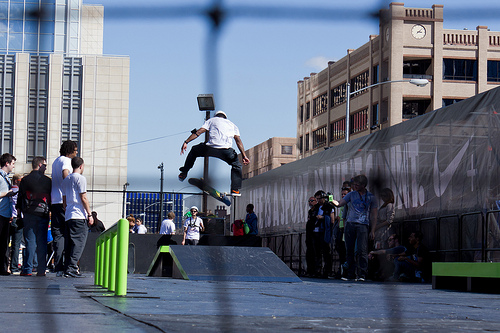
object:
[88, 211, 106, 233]
pole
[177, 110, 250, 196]
man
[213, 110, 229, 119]
hat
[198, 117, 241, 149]
white shirt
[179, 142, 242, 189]
jeans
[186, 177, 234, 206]
skateboard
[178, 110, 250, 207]
trick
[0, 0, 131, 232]
building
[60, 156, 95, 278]
people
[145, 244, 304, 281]
ramp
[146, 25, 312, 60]
air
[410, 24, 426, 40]
clock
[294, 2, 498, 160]
building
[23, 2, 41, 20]
window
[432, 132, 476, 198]
nike logo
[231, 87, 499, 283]
banner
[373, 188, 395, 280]
woman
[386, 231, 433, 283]
man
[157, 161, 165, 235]
light post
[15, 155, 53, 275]
man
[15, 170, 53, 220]
black jacket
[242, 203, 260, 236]
man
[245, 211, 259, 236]
blue shirt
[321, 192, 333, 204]
camera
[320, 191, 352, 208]
held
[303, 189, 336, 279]
two people